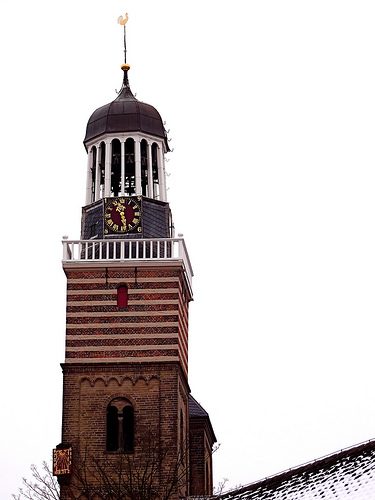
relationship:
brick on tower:
[62, 264, 195, 495] [47, 12, 213, 494]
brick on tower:
[168, 432, 186, 465] [47, 12, 213, 494]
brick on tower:
[159, 403, 166, 406] [47, 12, 213, 494]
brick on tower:
[144, 398, 151, 401] [47, 12, 213, 494]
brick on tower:
[139, 397, 148, 403] [47, 12, 213, 494]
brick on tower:
[94, 416, 100, 421] [47, 12, 213, 494]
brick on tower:
[145, 405, 176, 418] [34, 64, 229, 489]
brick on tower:
[77, 396, 92, 438] [47, 12, 213, 494]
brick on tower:
[170, 370, 175, 378] [47, 12, 213, 494]